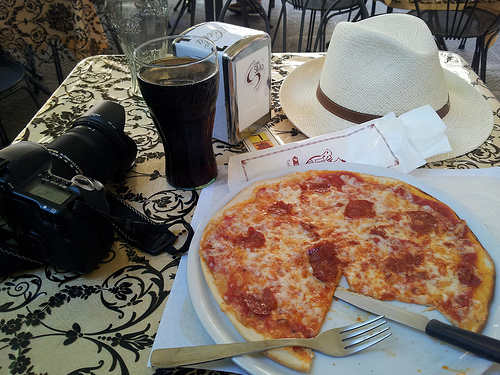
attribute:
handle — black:
[425, 318, 499, 364]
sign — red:
[335, 192, 385, 227]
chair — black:
[467, 2, 499, 81]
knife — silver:
[334, 285, 496, 370]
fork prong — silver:
[306, 302, 408, 366]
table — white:
[19, 18, 499, 340]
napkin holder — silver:
[170, 18, 277, 145]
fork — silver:
[152, 312, 395, 374]